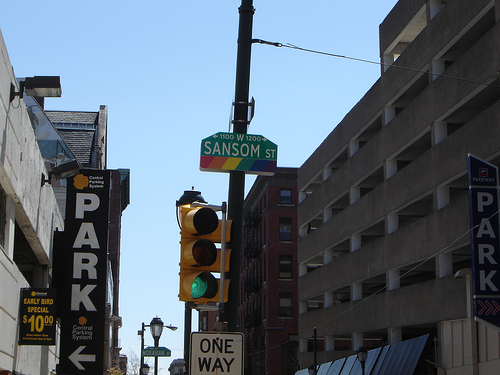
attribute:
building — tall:
[180, 0, 494, 368]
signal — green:
[181, 270, 221, 309]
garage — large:
[296, 3, 497, 371]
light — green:
[188, 276, 218, 305]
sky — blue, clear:
[0, 3, 399, 371]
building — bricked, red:
[213, 160, 299, 370]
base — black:
[134, 339, 172, 362]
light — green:
[185, 274, 214, 304]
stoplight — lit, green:
[175, 201, 232, 311]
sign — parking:
[65, 167, 103, 373]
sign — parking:
[18, 285, 58, 346]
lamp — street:
[148, 319, 173, 373]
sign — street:
[137, 345, 175, 358]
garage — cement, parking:
[299, 159, 447, 293]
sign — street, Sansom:
[196, 129, 280, 179]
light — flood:
[16, 75, 64, 102]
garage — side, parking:
[13, 125, 43, 276]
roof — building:
[47, 109, 92, 131]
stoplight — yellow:
[175, 196, 228, 311]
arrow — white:
[66, 347, 95, 369]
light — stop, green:
[171, 197, 234, 314]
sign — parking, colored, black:
[66, 167, 109, 372]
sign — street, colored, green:
[200, 132, 277, 173]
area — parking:
[6, 160, 24, 369]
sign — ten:
[17, 287, 54, 347]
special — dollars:
[23, 297, 55, 342]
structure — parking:
[294, 157, 462, 312]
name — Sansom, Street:
[200, 138, 273, 159]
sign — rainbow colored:
[194, 123, 364, 214]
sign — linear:
[463, 134, 495, 270]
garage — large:
[296, 101, 471, 300]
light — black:
[142, 311, 176, 372]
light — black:
[162, 191, 199, 218]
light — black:
[141, 314, 172, 346]